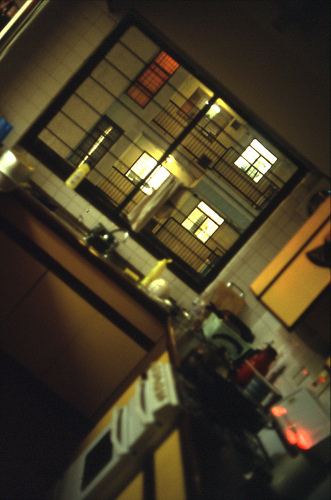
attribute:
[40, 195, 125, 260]
sink — kitchen, chrome, faucet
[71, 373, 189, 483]
oven — white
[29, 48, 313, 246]
window — kitchen, some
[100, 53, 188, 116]
light — red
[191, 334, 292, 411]
pot — tea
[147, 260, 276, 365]
board — wooden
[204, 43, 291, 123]
wall — tile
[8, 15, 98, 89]
tile — white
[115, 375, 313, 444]
cooker — gas, white, metallic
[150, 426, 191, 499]
drawer — wooden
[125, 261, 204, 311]
soap — dish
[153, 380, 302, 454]
stove — small, white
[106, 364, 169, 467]
handle — double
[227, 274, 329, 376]
cabinet — yellow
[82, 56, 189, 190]
building — window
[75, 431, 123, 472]
glass — black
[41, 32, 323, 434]
kitchen — area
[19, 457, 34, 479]
floor — dark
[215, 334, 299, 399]
container — red